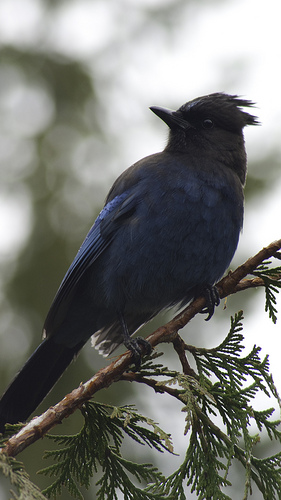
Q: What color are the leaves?
A: Green.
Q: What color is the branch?
A: Brown.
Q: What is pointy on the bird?
A: It's beak.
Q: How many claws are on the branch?
A: 2.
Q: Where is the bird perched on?
A: A branch.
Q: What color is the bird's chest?
A: Blue.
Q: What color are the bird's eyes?
A: Black.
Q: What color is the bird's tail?
A: Black.